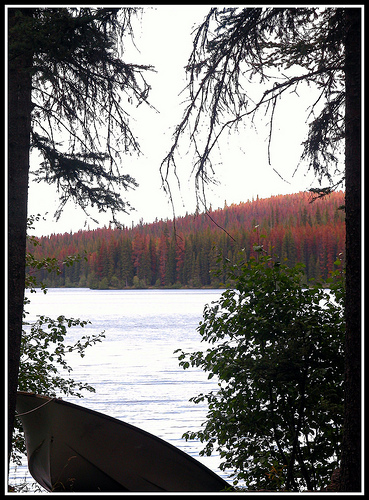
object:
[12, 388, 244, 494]
boat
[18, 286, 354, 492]
lake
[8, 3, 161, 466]
trees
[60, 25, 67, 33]
leaves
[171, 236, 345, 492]
bushes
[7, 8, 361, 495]
background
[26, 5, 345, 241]
sky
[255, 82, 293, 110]
twigs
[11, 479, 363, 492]
shore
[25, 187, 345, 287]
hill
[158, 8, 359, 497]
tree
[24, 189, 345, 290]
tree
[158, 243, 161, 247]
leaves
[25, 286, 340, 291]
shoreline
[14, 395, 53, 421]
rope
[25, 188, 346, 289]
forest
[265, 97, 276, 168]
branches